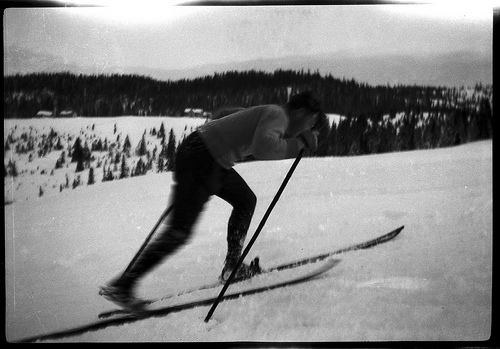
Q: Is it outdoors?
A: Yes, it is outdoors.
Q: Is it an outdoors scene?
A: Yes, it is outdoors.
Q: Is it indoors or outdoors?
A: It is outdoors.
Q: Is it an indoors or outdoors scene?
A: It is outdoors.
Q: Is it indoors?
A: No, it is outdoors.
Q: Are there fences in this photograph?
A: No, there are no fences.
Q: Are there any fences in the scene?
A: No, there are no fences.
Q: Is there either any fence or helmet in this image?
A: No, there are no fences or helmets.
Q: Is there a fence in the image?
A: No, there are no fences.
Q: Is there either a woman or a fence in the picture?
A: No, there are no fences or women.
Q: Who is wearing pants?
A: The man is wearing pants.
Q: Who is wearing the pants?
A: The man is wearing pants.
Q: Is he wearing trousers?
A: Yes, the man is wearing trousers.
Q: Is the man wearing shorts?
A: No, the man is wearing trousers.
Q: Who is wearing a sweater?
A: The man is wearing a sweater.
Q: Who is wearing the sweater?
A: The man is wearing a sweater.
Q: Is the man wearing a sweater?
A: Yes, the man is wearing a sweater.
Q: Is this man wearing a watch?
A: No, the man is wearing a sweater.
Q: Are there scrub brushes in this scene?
A: No, there are no scrub brushes.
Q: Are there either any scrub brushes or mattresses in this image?
A: No, there are no scrub brushes or mattresses.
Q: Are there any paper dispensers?
A: No, there are no paper dispensers.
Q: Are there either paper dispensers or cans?
A: No, there are no paper dispensers or cans.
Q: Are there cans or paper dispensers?
A: No, there are no paper dispensers or cans.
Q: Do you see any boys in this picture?
A: No, there are no boys.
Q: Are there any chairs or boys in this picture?
A: No, there are no boys or chairs.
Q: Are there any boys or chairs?
A: No, there are no boys or chairs.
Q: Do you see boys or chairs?
A: No, there are no boys or chairs.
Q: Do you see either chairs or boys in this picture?
A: No, there are no boys or chairs.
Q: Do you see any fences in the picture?
A: No, there are no fences.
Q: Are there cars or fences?
A: No, there are no fences or cars.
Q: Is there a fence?
A: No, there are no fences.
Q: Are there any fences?
A: No, there are no fences.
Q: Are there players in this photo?
A: No, there are no players.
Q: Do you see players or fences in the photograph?
A: No, there are no players or fences.